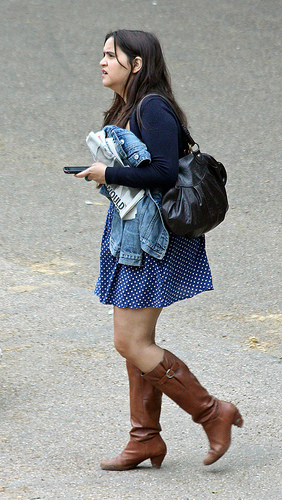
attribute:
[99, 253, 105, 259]
dot — white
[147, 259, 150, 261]
dot — white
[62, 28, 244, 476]
person — standing up